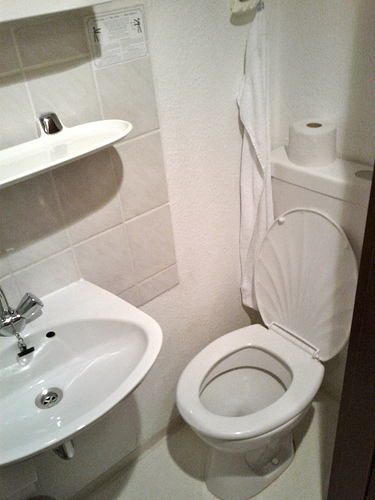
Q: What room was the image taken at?
A: It was taken at the bathroom.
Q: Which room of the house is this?
A: It is a bathroom.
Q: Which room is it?
A: It is a bathroom.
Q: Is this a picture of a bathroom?
A: Yes, it is showing a bathroom.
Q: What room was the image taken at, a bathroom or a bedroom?
A: It was taken at a bathroom.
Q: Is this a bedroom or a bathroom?
A: It is a bathroom.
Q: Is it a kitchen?
A: No, it is a bathroom.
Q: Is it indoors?
A: Yes, it is indoors.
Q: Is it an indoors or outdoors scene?
A: It is indoors.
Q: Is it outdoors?
A: No, it is indoors.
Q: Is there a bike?
A: No, there are no bikes.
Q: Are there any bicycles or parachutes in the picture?
A: No, there are no bicycles or parachutes.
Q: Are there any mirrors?
A: No, there are no mirrors.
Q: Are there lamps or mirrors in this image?
A: No, there are no mirrors or lamps.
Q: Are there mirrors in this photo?
A: No, there are no mirrors.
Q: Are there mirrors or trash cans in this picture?
A: No, there are no mirrors or trash cans.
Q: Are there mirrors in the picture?
A: No, there are no mirrors.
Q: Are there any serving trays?
A: No, there are no serving trays.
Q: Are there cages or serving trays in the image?
A: No, there are no serving trays or cages.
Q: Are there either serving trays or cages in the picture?
A: No, there are no serving trays or cages.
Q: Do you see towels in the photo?
A: Yes, there is a towel.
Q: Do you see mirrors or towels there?
A: Yes, there is a towel.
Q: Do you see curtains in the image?
A: No, there are no curtains.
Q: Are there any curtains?
A: No, there are no curtains.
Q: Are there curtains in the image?
A: No, there are no curtains.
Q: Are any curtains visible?
A: No, there are no curtains.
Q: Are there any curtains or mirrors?
A: No, there are no curtains or mirrors.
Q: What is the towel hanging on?
A: The towel is hanging on the wall.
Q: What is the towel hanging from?
A: The towel is hanging from the wall.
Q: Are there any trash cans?
A: No, there are no trash cans.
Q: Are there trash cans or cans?
A: No, there are no trash cans or cans.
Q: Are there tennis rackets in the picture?
A: No, there are no tennis rackets.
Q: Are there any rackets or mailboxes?
A: No, there are no rackets or mailboxes.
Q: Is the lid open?
A: Yes, the lid is open.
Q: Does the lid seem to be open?
A: Yes, the lid is open.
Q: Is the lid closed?
A: No, the lid is open.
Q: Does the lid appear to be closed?
A: No, the lid is open.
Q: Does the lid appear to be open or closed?
A: The lid is open.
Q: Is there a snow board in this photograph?
A: No, there are no snowboards.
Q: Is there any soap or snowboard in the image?
A: No, there are no snowboards or soaps.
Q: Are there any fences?
A: No, there are no fences.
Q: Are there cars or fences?
A: No, there are no fences or cars.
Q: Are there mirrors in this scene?
A: No, there are no mirrors.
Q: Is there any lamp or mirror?
A: No, there are no mirrors or lamps.